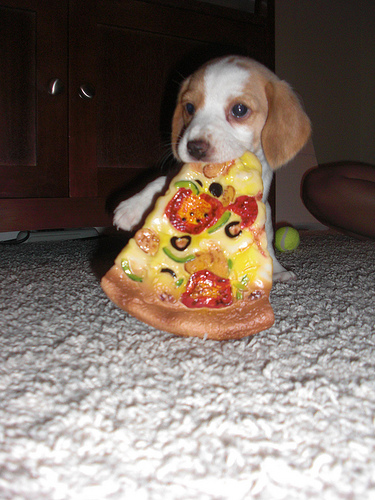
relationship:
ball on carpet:
[273, 227, 301, 254] [1, 225, 372, 499]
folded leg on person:
[305, 158, 374, 246] [284, 123, 373, 253]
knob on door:
[49, 75, 63, 99] [12, 28, 114, 166]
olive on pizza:
[167, 230, 197, 255] [142, 163, 272, 324]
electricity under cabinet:
[10, 217, 110, 250] [4, 174, 115, 245]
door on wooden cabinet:
[3, 2, 70, 198] [0, 0, 275, 228]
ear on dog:
[260, 77, 312, 170] [110, 50, 305, 285]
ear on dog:
[166, 68, 197, 136] [172, 47, 333, 280]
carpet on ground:
[1, 225, 372, 499] [6, 307, 228, 488]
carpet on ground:
[1, 225, 372, 499] [43, 360, 163, 483]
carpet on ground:
[1, 225, 372, 499] [227, 341, 333, 448]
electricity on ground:
[10, 217, 110, 250] [5, 242, 111, 298]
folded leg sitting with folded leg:
[299, 161, 375, 240] [299, 161, 375, 240]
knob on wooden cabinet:
[75, 81, 95, 100] [0, 0, 275, 228]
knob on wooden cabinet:
[44, 75, 63, 95] [0, 0, 275, 228]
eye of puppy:
[224, 93, 259, 131] [153, 57, 319, 276]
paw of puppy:
[112, 182, 145, 230] [112, 53, 311, 281]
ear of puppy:
[258, 75, 313, 173] [111, 47, 295, 286]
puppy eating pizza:
[164, 56, 314, 166] [118, 163, 278, 339]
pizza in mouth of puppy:
[99, 148, 275, 340] [112, 53, 311, 281]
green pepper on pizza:
[171, 177, 199, 194] [87, 147, 301, 343]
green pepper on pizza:
[159, 243, 197, 264] [87, 147, 301, 343]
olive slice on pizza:
[223, 218, 241, 239] [99, 148, 275, 340]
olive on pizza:
[167, 230, 197, 255] [99, 148, 275, 340]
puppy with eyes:
[111, 56, 313, 285] [184, 102, 248, 118]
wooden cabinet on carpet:
[4, 0, 274, 231] [1, 225, 372, 499]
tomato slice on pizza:
[166, 187, 219, 237] [99, 148, 275, 340]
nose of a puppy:
[187, 142, 209, 155] [112, 53, 311, 281]